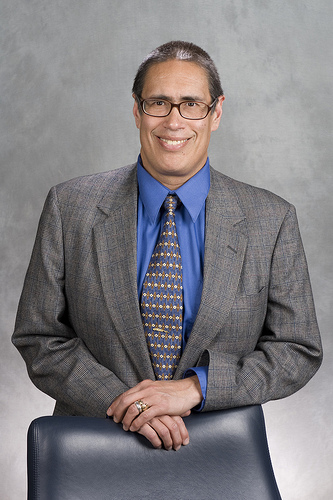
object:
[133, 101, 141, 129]
ear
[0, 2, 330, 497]
wall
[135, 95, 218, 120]
eyeglasses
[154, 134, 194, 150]
mouth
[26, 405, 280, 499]
chair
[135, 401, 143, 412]
ring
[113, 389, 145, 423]
finger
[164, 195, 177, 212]
knot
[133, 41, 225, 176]
head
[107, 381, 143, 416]
fingers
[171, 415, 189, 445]
fingers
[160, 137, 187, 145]
teeth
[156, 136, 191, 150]
lips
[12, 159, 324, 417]
blazer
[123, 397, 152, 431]
rings finger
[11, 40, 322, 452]
man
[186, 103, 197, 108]
eye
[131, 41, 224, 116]
hair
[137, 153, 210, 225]
collar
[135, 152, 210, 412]
man's shirt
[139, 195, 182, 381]
tie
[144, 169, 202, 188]
neck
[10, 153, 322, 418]
suit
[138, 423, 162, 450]
finger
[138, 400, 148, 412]
ring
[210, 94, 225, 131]
ear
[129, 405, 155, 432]
finger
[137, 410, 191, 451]
hands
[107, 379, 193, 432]
hands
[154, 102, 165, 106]
eye